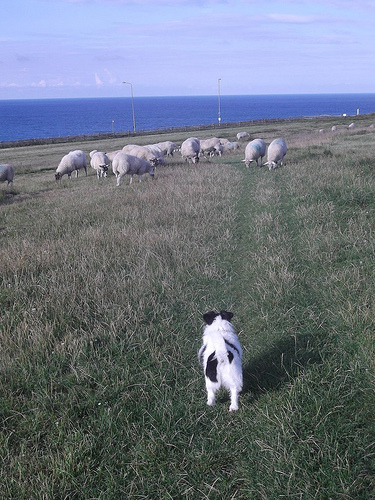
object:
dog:
[197, 310, 244, 411]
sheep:
[263, 137, 288, 170]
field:
[0, 113, 375, 498]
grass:
[280, 352, 347, 459]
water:
[5, 100, 71, 121]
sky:
[0, 4, 185, 71]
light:
[213, 70, 231, 133]